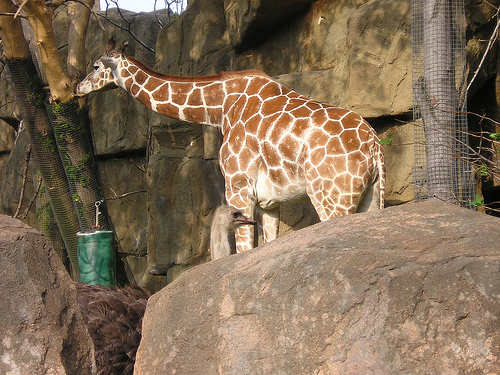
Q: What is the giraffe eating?
A: Bark from the tree.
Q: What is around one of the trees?
A: Fencing.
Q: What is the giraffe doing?
A: Eating.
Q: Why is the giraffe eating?
A: He is hungry and likes bark.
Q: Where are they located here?
A: At the zoo.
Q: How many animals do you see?
A: Two.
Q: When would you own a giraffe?
A: You wouldn't be allowed to own one.